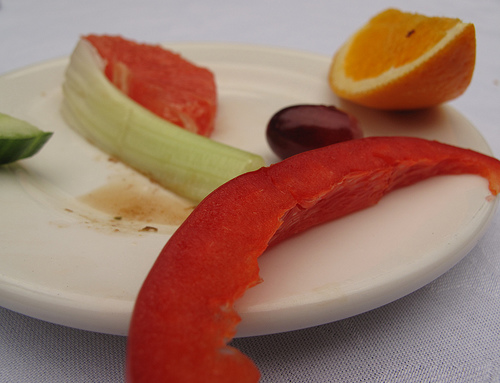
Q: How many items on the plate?
A: Six.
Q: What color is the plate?
A: White.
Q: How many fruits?
A: Three.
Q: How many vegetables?
A: Three.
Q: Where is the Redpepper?
A: Hanging off the plate.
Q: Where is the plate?
A: Table.